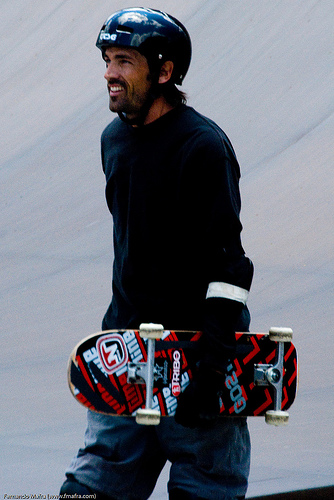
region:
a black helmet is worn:
[86, 5, 195, 111]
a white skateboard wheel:
[133, 407, 164, 425]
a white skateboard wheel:
[139, 319, 164, 337]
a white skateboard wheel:
[265, 408, 290, 425]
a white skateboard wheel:
[267, 323, 291, 340]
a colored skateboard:
[73, 323, 308, 428]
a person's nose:
[102, 65, 117, 82]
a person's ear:
[157, 60, 175, 85]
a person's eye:
[117, 55, 135, 67]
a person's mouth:
[104, 81, 124, 100]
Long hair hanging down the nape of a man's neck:
[152, 78, 201, 112]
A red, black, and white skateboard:
[65, 316, 317, 425]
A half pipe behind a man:
[3, 21, 316, 231]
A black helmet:
[89, 4, 224, 84]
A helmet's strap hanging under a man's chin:
[112, 74, 170, 123]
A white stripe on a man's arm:
[196, 264, 264, 306]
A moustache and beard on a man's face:
[100, 74, 161, 113]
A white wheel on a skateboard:
[137, 319, 167, 341]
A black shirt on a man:
[90, 112, 250, 303]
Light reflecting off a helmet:
[113, 9, 152, 27]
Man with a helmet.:
[84, 19, 216, 143]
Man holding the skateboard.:
[35, 216, 291, 443]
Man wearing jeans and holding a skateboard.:
[85, 21, 302, 495]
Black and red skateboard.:
[61, 307, 294, 437]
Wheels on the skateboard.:
[134, 291, 316, 441]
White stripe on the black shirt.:
[199, 226, 307, 353]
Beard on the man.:
[84, 27, 194, 141]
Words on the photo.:
[13, 488, 33, 498]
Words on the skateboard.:
[162, 332, 220, 413]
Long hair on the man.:
[140, 52, 201, 137]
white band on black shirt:
[197, 271, 284, 313]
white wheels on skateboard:
[128, 317, 165, 345]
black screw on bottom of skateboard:
[259, 363, 298, 394]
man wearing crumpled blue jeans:
[70, 416, 250, 490]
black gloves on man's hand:
[194, 294, 263, 370]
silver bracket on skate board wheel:
[127, 331, 165, 415]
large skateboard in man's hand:
[68, 319, 324, 424]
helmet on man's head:
[75, 11, 232, 63]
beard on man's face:
[62, 88, 147, 114]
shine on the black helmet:
[107, 14, 189, 45]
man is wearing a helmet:
[135, 17, 195, 112]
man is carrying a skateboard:
[89, 317, 307, 425]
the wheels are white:
[137, 325, 299, 431]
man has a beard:
[98, 77, 159, 119]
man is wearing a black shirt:
[121, 107, 246, 265]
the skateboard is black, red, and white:
[98, 331, 288, 422]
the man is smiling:
[88, 76, 150, 116]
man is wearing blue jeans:
[92, 417, 247, 491]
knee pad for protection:
[44, 469, 92, 497]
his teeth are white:
[97, 75, 135, 100]